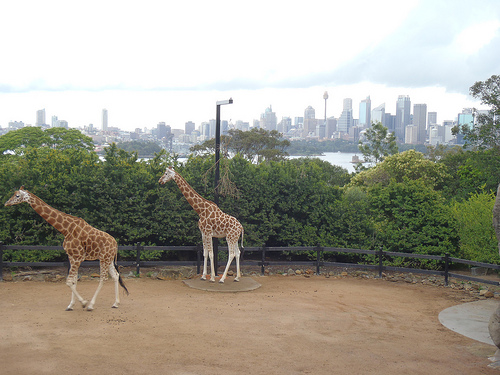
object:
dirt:
[0, 275, 499, 374]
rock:
[282, 268, 312, 278]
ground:
[352, 277, 373, 289]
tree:
[356, 120, 399, 164]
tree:
[187, 125, 292, 162]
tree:
[0, 123, 93, 154]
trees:
[442, 183, 500, 274]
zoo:
[0, 127, 499, 374]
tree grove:
[0, 140, 500, 262]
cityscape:
[0, 89, 500, 173]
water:
[82, 149, 446, 176]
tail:
[239, 222, 245, 261]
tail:
[112, 248, 130, 300]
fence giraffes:
[149, 168, 246, 295]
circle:
[181, 275, 261, 292]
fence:
[0, 244, 499, 288]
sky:
[0, 0, 499, 104]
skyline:
[0, 72, 499, 153]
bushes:
[0, 75, 500, 270]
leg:
[202, 241, 207, 276]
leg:
[209, 243, 216, 276]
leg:
[220, 249, 235, 279]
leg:
[235, 248, 242, 278]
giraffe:
[2, 183, 129, 311]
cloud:
[219, 19, 477, 100]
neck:
[173, 172, 207, 210]